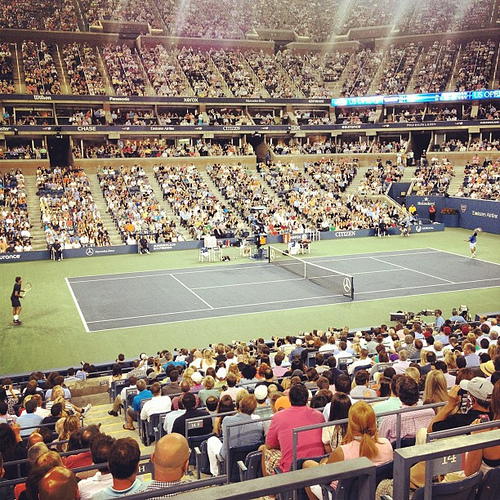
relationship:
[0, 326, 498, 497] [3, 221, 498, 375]
spectators watching match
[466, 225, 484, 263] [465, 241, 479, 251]
player wearing white shorts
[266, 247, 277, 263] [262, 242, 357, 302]
mercedes symbol on net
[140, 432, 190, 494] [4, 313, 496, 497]
spectator in stand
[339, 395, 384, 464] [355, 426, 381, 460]
hair tied in a pony tail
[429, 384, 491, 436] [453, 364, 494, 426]
guy using binoculars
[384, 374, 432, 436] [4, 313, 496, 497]
spectator in stand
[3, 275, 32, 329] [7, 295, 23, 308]
tennis player wearing shirt shorts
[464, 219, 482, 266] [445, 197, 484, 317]
tennis player wearing shorts shirt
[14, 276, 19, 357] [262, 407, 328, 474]
man has shirt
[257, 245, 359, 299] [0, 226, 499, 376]
net in middle of court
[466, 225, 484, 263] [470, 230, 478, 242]
player wearing shirt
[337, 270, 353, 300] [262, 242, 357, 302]
mercedes on net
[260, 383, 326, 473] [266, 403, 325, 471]
man wearing shirt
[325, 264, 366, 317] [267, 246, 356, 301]
symbol on net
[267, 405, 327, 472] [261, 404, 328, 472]
man wearing pink shirt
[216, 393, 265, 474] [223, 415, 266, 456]
man wearing shirt